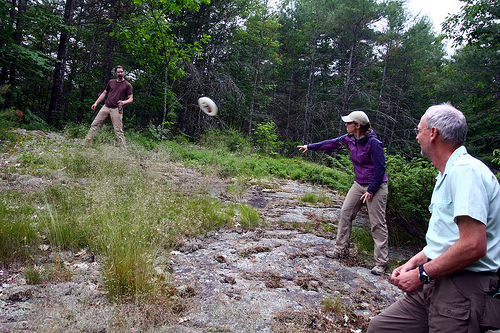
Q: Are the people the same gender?
A: No, they are both male and female.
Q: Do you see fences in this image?
A: No, there are no fences.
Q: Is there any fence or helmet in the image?
A: No, there are no fences or helmets.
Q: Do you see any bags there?
A: No, there are no bags.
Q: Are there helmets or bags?
A: No, there are no bags or helmets.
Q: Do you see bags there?
A: No, there are no bags.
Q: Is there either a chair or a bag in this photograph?
A: No, there are no bags or chairs.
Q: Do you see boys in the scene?
A: No, there are no boys.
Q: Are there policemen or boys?
A: No, there are no boys or policemen.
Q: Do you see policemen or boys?
A: No, there are no boys or policemen.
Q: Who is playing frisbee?
A: The man is playing frisbee.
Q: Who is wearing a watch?
A: The man is wearing a watch.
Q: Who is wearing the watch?
A: The man is wearing a watch.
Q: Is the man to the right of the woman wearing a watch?
A: Yes, the man is wearing a watch.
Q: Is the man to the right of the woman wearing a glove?
A: No, the man is wearing a watch.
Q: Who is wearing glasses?
A: The man is wearing glasses.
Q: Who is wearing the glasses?
A: The man is wearing glasses.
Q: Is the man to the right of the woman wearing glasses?
A: Yes, the man is wearing glasses.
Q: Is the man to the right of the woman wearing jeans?
A: No, the man is wearing glasses.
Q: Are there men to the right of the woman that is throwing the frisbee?
A: Yes, there is a man to the right of the woman.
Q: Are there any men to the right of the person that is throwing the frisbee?
A: Yes, there is a man to the right of the woman.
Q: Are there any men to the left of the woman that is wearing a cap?
A: No, the man is to the right of the woman.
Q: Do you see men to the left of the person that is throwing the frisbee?
A: No, the man is to the right of the woman.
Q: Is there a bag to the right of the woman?
A: No, there is a man to the right of the woman.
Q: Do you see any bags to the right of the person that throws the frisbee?
A: No, there is a man to the right of the woman.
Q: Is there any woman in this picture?
A: Yes, there is a woman.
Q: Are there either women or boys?
A: Yes, there is a woman.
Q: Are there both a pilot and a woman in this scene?
A: No, there is a woman but no pilots.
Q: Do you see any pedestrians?
A: No, there are no pedestrians.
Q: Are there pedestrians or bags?
A: No, there are no pedestrians or bags.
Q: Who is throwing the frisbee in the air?
A: The woman is throwing the frisbee.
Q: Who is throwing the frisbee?
A: The woman is throwing the frisbee.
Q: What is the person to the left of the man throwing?
A: The woman is throwing the frisbee.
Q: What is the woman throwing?
A: The woman is throwing the frisbee.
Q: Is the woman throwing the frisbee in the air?
A: Yes, the woman is throwing the frisbee.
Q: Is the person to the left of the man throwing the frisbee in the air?
A: Yes, the woman is throwing the frisbee.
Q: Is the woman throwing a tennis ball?
A: No, the woman is throwing the frisbee.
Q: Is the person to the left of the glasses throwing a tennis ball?
A: No, the woman is throwing the frisbee.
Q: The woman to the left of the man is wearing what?
A: The woman is wearing a cap.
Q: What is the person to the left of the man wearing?
A: The woman is wearing a cap.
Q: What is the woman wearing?
A: The woman is wearing a cap.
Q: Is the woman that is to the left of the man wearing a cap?
A: Yes, the woman is wearing a cap.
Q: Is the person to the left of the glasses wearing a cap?
A: Yes, the woman is wearing a cap.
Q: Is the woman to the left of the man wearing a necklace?
A: No, the woman is wearing a cap.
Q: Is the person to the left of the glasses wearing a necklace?
A: No, the woman is wearing a cap.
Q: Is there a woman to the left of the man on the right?
A: Yes, there is a woman to the left of the man.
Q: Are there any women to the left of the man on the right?
A: Yes, there is a woman to the left of the man.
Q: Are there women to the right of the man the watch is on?
A: No, the woman is to the left of the man.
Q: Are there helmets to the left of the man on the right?
A: No, there is a woman to the left of the man.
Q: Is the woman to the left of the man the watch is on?
A: Yes, the woman is to the left of the man.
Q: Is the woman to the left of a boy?
A: No, the woman is to the left of the man.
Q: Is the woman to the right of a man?
A: No, the woman is to the left of a man.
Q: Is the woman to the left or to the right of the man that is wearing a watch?
A: The woman is to the left of the man.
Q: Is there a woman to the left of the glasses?
A: Yes, there is a woman to the left of the glasses.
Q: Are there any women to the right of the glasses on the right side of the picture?
A: No, the woman is to the left of the glasses.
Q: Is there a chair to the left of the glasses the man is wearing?
A: No, there is a woman to the left of the glasses.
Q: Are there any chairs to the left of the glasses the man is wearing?
A: No, there is a woman to the left of the glasses.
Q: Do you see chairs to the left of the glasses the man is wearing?
A: No, there is a woman to the left of the glasses.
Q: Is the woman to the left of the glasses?
A: Yes, the woman is to the left of the glasses.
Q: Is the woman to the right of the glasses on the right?
A: No, the woman is to the left of the glasses.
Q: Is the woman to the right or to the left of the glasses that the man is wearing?
A: The woman is to the left of the glasses.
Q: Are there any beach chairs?
A: No, there are no beach chairs.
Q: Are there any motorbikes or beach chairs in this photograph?
A: No, there are no beach chairs or motorbikes.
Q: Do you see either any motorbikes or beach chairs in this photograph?
A: No, there are no beach chairs or motorbikes.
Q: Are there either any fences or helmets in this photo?
A: No, there are no fences or helmets.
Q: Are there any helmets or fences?
A: No, there are no fences or helmets.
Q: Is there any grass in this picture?
A: Yes, there is grass.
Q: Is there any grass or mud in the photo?
A: Yes, there is grass.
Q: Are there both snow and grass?
A: No, there is grass but no snow.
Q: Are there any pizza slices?
A: No, there are no pizza slices.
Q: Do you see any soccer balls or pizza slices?
A: No, there are no pizza slices or soccer balls.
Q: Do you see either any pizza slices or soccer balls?
A: No, there are no pizza slices or soccer balls.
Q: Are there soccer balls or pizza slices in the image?
A: No, there are no pizza slices or soccer balls.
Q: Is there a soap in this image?
A: No, there are no soaps.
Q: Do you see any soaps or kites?
A: No, there are no soaps or kites.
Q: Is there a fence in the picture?
A: No, there are no fences.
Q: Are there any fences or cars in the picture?
A: No, there are no fences or cars.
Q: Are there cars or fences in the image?
A: No, there are no fences or cars.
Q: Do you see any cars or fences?
A: No, there are no fences or cars.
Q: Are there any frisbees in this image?
A: Yes, there is a frisbee.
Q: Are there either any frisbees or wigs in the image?
A: Yes, there is a frisbee.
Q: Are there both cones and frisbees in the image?
A: No, there is a frisbee but no cones.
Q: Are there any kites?
A: No, there are no kites.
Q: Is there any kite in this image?
A: No, there are no kites.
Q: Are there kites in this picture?
A: No, there are no kites.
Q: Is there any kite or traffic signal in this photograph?
A: No, there are no kites or traffic lights.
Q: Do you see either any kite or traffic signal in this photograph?
A: No, there are no kites or traffic lights.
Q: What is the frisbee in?
A: The frisbee is in the air.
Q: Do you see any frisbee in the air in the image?
A: Yes, there is a frisbee in the air.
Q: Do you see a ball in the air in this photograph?
A: No, there is a frisbee in the air.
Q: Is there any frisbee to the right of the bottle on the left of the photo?
A: Yes, there is a frisbee to the right of the bottle.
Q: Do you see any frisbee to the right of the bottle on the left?
A: Yes, there is a frisbee to the right of the bottle.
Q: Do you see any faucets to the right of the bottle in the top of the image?
A: No, there is a frisbee to the right of the bottle.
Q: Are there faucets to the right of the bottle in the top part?
A: No, there is a frisbee to the right of the bottle.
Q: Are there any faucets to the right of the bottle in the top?
A: No, there is a frisbee to the right of the bottle.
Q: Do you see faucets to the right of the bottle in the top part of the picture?
A: No, there is a frisbee to the right of the bottle.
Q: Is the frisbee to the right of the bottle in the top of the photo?
A: Yes, the frisbee is to the right of the bottle.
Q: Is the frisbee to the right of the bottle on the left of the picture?
A: Yes, the frisbee is to the right of the bottle.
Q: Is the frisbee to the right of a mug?
A: No, the frisbee is to the right of the bottle.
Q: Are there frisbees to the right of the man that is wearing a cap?
A: Yes, there is a frisbee to the right of the man.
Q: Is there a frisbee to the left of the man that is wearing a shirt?
A: No, the frisbee is to the right of the man.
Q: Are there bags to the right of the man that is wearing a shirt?
A: No, there is a frisbee to the right of the man.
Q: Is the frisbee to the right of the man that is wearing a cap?
A: Yes, the frisbee is to the right of the man.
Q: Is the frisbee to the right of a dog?
A: No, the frisbee is to the right of the man.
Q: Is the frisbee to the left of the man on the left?
A: No, the frisbee is to the right of the man.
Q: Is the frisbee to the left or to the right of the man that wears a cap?
A: The frisbee is to the right of the man.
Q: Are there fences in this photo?
A: No, there are no fences.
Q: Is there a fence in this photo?
A: No, there are no fences.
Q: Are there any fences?
A: No, there are no fences.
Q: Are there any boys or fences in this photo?
A: No, there are no fences or boys.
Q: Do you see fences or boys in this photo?
A: No, there are no fences or boys.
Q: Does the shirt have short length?
A: Yes, the shirt is short.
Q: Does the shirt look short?
A: Yes, the shirt is short.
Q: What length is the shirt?
A: The shirt is short.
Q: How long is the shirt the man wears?
A: The shirt is short.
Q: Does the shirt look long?
A: No, the shirt is short.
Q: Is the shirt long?
A: No, the shirt is short.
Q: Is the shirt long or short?
A: The shirt is short.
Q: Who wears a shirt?
A: The man wears a shirt.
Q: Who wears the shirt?
A: The man wears a shirt.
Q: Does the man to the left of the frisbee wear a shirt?
A: Yes, the man wears a shirt.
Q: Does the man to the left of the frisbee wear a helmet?
A: No, the man wears a shirt.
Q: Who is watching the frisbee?
A: The man is watching the frisbee.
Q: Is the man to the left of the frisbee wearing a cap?
A: Yes, the man is wearing a cap.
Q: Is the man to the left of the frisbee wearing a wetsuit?
A: No, the man is wearing a cap.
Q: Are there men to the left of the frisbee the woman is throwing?
A: Yes, there is a man to the left of the frisbee.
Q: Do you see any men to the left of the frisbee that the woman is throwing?
A: Yes, there is a man to the left of the frisbee.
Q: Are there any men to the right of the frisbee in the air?
A: No, the man is to the left of the frisbee.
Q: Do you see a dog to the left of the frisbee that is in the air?
A: No, there is a man to the left of the frisbee.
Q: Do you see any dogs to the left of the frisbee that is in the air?
A: No, there is a man to the left of the frisbee.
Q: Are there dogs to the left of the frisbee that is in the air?
A: No, there is a man to the left of the frisbee.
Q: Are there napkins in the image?
A: No, there are no napkins.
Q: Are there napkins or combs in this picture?
A: No, there are no napkins or combs.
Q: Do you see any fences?
A: No, there are no fences.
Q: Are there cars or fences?
A: No, there are no fences or cars.